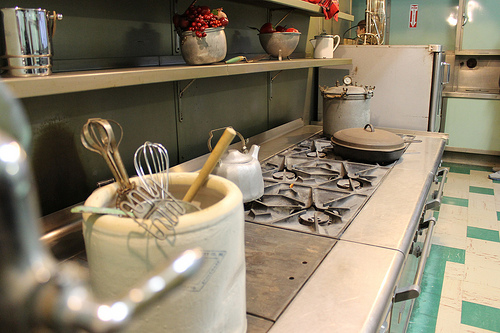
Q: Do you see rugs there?
A: No, there are no rugs.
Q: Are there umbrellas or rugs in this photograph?
A: No, there are no rugs or umbrellas.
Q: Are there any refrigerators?
A: Yes, there is a refrigerator.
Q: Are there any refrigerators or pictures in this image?
A: Yes, there is a refrigerator.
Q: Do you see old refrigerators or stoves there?
A: Yes, there is an old refrigerator.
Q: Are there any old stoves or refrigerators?
A: Yes, there is an old refrigerator.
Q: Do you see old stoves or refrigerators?
A: Yes, there is an old refrigerator.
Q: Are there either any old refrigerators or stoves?
A: Yes, there is an old refrigerator.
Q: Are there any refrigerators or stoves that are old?
A: Yes, the refrigerator is old.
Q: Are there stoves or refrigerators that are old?
A: Yes, the refrigerator is old.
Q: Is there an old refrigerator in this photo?
A: Yes, there is an old refrigerator.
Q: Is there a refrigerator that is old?
A: Yes, there is a refrigerator that is old.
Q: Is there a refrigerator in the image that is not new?
A: Yes, there is a old refrigerator.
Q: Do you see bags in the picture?
A: No, there are no bags.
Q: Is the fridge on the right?
A: Yes, the fridge is on the right of the image.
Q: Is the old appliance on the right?
A: Yes, the fridge is on the right of the image.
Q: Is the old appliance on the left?
A: No, the fridge is on the right of the image.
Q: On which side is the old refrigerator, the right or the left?
A: The refrigerator is on the right of the image.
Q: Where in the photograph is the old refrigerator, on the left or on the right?
A: The refrigerator is on the right of the image.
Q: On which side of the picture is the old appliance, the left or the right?
A: The refrigerator is on the right of the image.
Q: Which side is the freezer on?
A: The freezer is on the right of the image.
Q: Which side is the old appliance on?
A: The freezer is on the right of the image.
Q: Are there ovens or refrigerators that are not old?
A: No, there is a refrigerator but it is old.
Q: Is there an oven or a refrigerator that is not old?
A: No, there is a refrigerator but it is old.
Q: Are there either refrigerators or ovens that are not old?
A: No, there is a refrigerator but it is old.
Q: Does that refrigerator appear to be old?
A: Yes, the refrigerator is old.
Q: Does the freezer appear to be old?
A: Yes, the freezer is old.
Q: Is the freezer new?
A: No, the freezer is old.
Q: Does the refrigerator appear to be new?
A: No, the refrigerator is old.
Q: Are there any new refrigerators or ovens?
A: No, there is a refrigerator but it is old.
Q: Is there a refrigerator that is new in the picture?
A: No, there is a refrigerator but it is old.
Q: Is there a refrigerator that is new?
A: No, there is a refrigerator but it is old.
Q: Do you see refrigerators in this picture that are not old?
A: No, there is a refrigerator but it is old.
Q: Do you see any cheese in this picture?
A: No, there is no cheese.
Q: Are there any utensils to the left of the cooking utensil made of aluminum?
A: Yes, there is a utensil to the left of the tea kettle.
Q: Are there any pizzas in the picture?
A: No, there are no pizzas.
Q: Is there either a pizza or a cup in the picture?
A: No, there are no pizzas or cups.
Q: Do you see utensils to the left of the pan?
A: Yes, there is a utensil to the left of the pan.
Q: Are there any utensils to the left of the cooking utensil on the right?
A: Yes, there is a utensil to the left of the pan.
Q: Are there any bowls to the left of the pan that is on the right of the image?
A: No, there is a utensil to the left of the pan.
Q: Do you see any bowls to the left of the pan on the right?
A: No, there is a utensil to the left of the pan.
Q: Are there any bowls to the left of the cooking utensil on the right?
A: No, there is a utensil to the left of the pan.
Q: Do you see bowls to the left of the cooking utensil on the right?
A: No, there is a utensil to the left of the pan.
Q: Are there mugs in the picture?
A: No, there are no mugs.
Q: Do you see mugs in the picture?
A: No, there are no mugs.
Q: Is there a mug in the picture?
A: No, there are no mugs.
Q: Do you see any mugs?
A: No, there are no mugs.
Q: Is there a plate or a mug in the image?
A: No, there are no mugs or plates.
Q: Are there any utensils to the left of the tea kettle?
A: Yes, there is a utensil to the left of the tea kettle.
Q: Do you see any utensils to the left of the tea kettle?
A: Yes, there is a utensil to the left of the tea kettle.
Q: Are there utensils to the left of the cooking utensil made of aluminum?
A: Yes, there is a utensil to the left of the tea kettle.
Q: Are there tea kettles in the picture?
A: Yes, there is a tea kettle.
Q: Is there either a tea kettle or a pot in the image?
A: Yes, there is a tea kettle.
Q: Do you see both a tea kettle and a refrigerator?
A: Yes, there are both a tea kettle and a refrigerator.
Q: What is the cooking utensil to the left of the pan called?
A: The cooking utensil is a tea kettle.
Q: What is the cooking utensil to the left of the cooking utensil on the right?
A: The cooking utensil is a tea kettle.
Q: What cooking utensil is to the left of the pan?
A: The cooking utensil is a tea kettle.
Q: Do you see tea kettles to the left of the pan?
A: Yes, there is a tea kettle to the left of the pan.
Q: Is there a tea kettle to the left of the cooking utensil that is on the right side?
A: Yes, there is a tea kettle to the left of the pan.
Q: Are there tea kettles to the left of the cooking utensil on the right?
A: Yes, there is a tea kettle to the left of the pan.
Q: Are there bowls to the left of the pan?
A: No, there is a tea kettle to the left of the pan.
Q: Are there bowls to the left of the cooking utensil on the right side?
A: No, there is a tea kettle to the left of the pan.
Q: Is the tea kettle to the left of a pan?
A: Yes, the tea kettle is to the left of a pan.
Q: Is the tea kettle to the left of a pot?
A: No, the tea kettle is to the left of a pan.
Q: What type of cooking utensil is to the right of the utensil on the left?
A: The cooking utensil is a tea kettle.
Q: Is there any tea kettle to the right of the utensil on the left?
A: Yes, there is a tea kettle to the right of the utensil.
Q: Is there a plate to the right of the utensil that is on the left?
A: No, there is a tea kettle to the right of the utensil.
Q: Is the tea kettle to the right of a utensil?
A: Yes, the tea kettle is to the right of a utensil.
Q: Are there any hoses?
A: No, there are no hoses.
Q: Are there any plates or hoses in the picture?
A: No, there are no hoses or plates.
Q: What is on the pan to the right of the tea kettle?
A: The lid is on the pan.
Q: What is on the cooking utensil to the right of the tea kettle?
A: The lid is on the pan.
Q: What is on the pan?
A: The lid is on the pan.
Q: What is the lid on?
A: The lid is on the pan.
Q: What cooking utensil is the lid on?
A: The lid is on the pan.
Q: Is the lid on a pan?
A: Yes, the lid is on a pan.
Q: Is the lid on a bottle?
A: No, the lid is on a pan.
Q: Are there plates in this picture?
A: No, there are no plates.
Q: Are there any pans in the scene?
A: Yes, there is a pan.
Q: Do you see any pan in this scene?
A: Yes, there is a pan.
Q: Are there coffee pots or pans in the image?
A: Yes, there is a pan.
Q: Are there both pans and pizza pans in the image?
A: No, there is a pan but no pizza pans.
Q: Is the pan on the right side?
A: Yes, the pan is on the right of the image.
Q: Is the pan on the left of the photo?
A: No, the pan is on the right of the image.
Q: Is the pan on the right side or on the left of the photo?
A: The pan is on the right of the image.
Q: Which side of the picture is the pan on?
A: The pan is on the right of the image.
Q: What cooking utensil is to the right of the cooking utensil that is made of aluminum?
A: The cooking utensil is a pan.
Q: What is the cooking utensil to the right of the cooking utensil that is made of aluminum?
A: The cooking utensil is a pan.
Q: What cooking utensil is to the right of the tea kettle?
A: The cooking utensil is a pan.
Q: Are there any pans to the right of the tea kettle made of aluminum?
A: Yes, there is a pan to the right of the tea kettle.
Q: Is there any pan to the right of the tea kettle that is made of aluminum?
A: Yes, there is a pan to the right of the tea kettle.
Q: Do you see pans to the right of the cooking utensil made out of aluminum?
A: Yes, there is a pan to the right of the tea kettle.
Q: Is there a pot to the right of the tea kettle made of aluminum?
A: No, there is a pan to the right of the tea kettle.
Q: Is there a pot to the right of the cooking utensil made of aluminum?
A: No, there is a pan to the right of the tea kettle.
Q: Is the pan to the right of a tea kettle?
A: Yes, the pan is to the right of a tea kettle.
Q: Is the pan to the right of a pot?
A: No, the pan is to the right of a tea kettle.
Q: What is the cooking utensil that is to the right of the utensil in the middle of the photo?
A: The cooking utensil is a pan.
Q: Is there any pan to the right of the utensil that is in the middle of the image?
A: Yes, there is a pan to the right of the utensil.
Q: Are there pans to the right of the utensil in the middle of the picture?
A: Yes, there is a pan to the right of the utensil.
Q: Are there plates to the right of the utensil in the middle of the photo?
A: No, there is a pan to the right of the utensil.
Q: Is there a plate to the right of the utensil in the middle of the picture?
A: No, there is a pan to the right of the utensil.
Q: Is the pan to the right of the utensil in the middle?
A: Yes, the pan is to the right of the utensil.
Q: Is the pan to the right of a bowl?
A: No, the pan is to the right of the utensil.